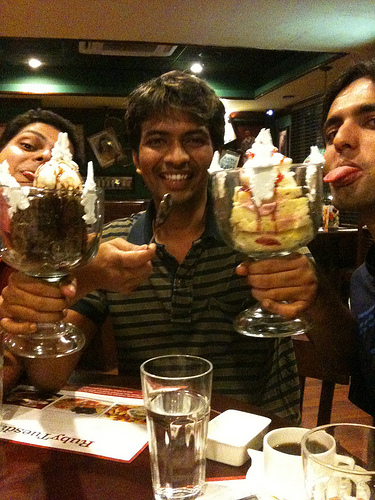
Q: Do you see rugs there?
A: No, there are no rugs.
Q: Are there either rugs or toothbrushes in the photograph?
A: No, there are no rugs or toothbrushes.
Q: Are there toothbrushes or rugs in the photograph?
A: No, there are no rugs or toothbrushes.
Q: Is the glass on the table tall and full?
A: Yes, the glass is tall and full.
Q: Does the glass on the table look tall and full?
A: Yes, the glass is tall and full.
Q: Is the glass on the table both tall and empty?
A: No, the glass is tall but full.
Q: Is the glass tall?
A: Yes, the glass is tall.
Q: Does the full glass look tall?
A: Yes, the glass is tall.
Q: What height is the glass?
A: The glass is tall.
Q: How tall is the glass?
A: The glass is tall.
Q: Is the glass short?
A: No, the glass is tall.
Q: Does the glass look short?
A: No, the glass is tall.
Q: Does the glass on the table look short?
A: No, the glass is tall.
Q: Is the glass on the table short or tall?
A: The glass is tall.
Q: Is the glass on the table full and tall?
A: Yes, the glass is full and tall.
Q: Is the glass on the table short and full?
A: No, the glass is full but tall.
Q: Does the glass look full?
A: Yes, the glass is full.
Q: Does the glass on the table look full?
A: Yes, the glass is full.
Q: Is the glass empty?
A: No, the glass is full.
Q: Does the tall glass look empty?
A: No, the glass is full.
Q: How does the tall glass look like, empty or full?
A: The glass is full.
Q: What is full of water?
A: The glass is full of water.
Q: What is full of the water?
A: The glass is full of water.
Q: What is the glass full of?
A: The glass is full of water.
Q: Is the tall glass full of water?
A: Yes, the glass is full of water.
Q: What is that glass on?
A: The glass is on the table.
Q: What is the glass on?
A: The glass is on the table.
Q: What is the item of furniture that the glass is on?
A: The piece of furniture is a table.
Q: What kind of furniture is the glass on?
A: The glass is on the table.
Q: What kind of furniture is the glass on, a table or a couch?
A: The glass is on a table.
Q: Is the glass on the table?
A: Yes, the glass is on the table.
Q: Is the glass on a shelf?
A: No, the glass is on the table.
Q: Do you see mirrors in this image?
A: No, there are no mirrors.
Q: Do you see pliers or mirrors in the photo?
A: No, there are no mirrors or pliers.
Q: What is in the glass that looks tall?
A: The water is in the glass.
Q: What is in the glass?
A: The water is in the glass.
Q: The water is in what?
A: The water is in the glass.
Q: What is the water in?
A: The water is in the glass.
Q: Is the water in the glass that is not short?
A: Yes, the water is in the glass.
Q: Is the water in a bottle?
A: No, the water is in the glass.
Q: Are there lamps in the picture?
A: No, there are no lamps.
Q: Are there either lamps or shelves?
A: No, there are no lamps or shelves.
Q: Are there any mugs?
A: Yes, there is a mug.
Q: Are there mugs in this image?
A: Yes, there is a mug.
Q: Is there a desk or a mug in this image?
A: Yes, there is a mug.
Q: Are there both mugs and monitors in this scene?
A: No, there is a mug but no monitors.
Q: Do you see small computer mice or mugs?
A: Yes, there is a small mug.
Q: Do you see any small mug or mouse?
A: Yes, there is a small mug.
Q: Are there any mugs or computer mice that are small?
A: Yes, the mug is small.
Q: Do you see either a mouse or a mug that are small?
A: Yes, the mug is small.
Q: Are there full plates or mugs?
A: Yes, there is a full mug.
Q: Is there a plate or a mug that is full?
A: Yes, the mug is full.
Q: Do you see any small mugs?
A: Yes, there is a small mug.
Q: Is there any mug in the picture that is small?
A: Yes, there is a mug that is small.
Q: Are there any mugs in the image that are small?
A: Yes, there is a mug that is small.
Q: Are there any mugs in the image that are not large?
A: Yes, there is a small mug.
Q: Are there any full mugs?
A: Yes, there is a full mug.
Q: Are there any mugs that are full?
A: Yes, there is a mug that is full.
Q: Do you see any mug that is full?
A: Yes, there is a mug that is full.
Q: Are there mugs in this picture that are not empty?
A: Yes, there is an full mug.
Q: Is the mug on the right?
A: Yes, the mug is on the right of the image.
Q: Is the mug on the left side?
A: No, the mug is on the right of the image.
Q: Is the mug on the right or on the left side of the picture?
A: The mug is on the right of the image.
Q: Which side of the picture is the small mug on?
A: The mug is on the right of the image.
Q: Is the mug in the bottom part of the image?
A: Yes, the mug is in the bottom of the image.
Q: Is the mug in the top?
A: No, the mug is in the bottom of the image.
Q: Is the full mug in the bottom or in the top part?
A: The mug is in the bottom of the image.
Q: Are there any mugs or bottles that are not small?
A: No, there is a mug but it is small.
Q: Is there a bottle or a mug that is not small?
A: No, there is a mug but it is small.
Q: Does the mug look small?
A: Yes, the mug is small.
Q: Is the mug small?
A: Yes, the mug is small.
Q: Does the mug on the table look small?
A: Yes, the mug is small.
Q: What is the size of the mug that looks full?
A: The mug is small.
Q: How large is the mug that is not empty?
A: The mug is small.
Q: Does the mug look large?
A: No, the mug is small.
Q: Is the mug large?
A: No, the mug is small.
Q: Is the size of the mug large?
A: No, the mug is small.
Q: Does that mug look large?
A: No, the mug is small.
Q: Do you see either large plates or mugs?
A: No, there is a mug but it is small.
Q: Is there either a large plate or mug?
A: No, there is a mug but it is small.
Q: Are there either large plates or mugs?
A: No, there is a mug but it is small.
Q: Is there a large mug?
A: No, there is a mug but it is small.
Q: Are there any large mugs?
A: No, there is a mug but it is small.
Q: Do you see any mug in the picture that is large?
A: No, there is a mug but it is small.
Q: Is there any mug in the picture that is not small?
A: No, there is a mug but it is small.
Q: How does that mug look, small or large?
A: The mug is small.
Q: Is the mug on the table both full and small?
A: Yes, the mug is full and small.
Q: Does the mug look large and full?
A: No, the mug is full but small.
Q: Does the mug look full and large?
A: No, the mug is full but small.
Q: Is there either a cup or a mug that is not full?
A: No, there is a mug but it is full.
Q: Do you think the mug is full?
A: Yes, the mug is full.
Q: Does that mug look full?
A: Yes, the mug is full.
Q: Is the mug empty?
A: No, the mug is full.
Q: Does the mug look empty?
A: No, the mug is full.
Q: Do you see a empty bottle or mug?
A: No, there is a mug but it is full.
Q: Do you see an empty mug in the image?
A: No, there is a mug but it is full.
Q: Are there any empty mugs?
A: No, there is a mug but it is full.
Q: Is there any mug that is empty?
A: No, there is a mug but it is full.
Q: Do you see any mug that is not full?
A: No, there is a mug but it is full.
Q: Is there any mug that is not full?
A: No, there is a mug but it is full.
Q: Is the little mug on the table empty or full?
A: The mug is full.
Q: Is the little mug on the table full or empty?
A: The mug is full.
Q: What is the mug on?
A: The mug is on the table.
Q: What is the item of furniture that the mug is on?
A: The piece of furniture is a table.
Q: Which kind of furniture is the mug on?
A: The mug is on the table.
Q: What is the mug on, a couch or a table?
A: The mug is on a table.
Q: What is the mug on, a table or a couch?
A: The mug is on a table.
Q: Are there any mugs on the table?
A: Yes, there is a mug on the table.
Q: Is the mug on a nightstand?
A: No, the mug is on the table.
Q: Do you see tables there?
A: Yes, there is a table.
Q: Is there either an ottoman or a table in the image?
A: Yes, there is a table.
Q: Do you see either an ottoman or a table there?
A: Yes, there is a table.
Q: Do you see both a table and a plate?
A: No, there is a table but no plates.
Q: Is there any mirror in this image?
A: No, there are no mirrors.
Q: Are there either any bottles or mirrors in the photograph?
A: No, there are no mirrors or bottles.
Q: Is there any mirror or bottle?
A: No, there are no mirrors or bottles.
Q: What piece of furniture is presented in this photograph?
A: The piece of furniture is a table.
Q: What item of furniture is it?
A: The piece of furniture is a table.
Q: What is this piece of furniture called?
A: This is a table.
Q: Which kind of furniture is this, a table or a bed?
A: This is a table.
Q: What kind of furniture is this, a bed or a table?
A: This is a table.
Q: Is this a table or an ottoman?
A: This is a table.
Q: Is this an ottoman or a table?
A: This is a table.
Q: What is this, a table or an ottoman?
A: This is a table.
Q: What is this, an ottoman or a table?
A: This is a table.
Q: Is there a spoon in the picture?
A: Yes, there is a spoon.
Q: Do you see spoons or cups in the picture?
A: Yes, there is a spoon.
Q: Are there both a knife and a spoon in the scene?
A: No, there is a spoon but no knives.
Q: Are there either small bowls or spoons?
A: Yes, there is a small spoon.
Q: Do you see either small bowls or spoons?
A: Yes, there is a small spoon.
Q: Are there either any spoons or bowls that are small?
A: Yes, the spoon is small.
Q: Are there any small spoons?
A: Yes, there is a small spoon.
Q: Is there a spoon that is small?
A: Yes, there is a spoon that is small.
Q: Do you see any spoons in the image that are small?
A: Yes, there is a spoon that is small.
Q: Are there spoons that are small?
A: Yes, there is a spoon that is small.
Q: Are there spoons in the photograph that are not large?
A: Yes, there is a small spoon.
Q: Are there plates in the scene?
A: No, there are no plates.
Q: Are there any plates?
A: No, there are no plates.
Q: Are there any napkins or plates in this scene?
A: No, there are no plates or napkins.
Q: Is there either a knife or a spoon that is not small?
A: No, there is a spoon but it is small.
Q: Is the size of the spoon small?
A: Yes, the spoon is small.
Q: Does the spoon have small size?
A: Yes, the spoon is small.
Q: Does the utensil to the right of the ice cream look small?
A: Yes, the spoon is small.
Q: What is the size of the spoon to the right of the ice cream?
A: The spoon is small.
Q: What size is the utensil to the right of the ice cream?
A: The spoon is small.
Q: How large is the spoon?
A: The spoon is small.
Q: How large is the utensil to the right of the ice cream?
A: The spoon is small.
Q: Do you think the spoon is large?
A: No, the spoon is small.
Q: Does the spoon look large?
A: No, the spoon is small.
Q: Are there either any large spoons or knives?
A: No, there is a spoon but it is small.